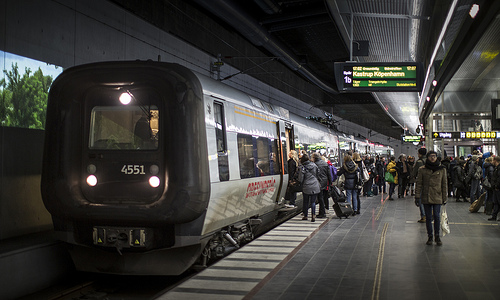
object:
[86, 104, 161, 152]
windshield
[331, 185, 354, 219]
bag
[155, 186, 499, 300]
platform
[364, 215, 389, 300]
stripe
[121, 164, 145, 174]
numbers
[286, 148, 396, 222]
people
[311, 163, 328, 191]
luggage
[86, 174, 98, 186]
light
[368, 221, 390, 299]
lines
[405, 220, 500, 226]
lines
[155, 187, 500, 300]
ground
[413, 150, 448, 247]
man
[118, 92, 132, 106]
white towels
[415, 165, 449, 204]
jacket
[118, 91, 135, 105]
lights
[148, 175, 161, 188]
lights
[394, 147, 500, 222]
people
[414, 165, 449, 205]
coat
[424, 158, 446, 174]
scarf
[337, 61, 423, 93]
sign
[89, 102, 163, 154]
window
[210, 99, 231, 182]
window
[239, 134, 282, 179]
window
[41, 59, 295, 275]
train car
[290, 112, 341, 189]
train car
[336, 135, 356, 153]
train car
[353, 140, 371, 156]
train car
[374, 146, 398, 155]
train car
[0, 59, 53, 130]
trees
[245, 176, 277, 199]
logo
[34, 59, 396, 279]
train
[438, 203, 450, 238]
bag